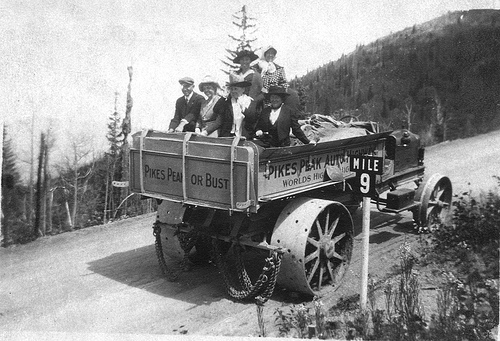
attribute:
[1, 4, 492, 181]
mountains — in background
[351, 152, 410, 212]
sign — mile marker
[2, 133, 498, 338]
dirt road — steep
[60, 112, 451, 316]
truck — large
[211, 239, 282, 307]
chain — large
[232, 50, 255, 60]
hat — large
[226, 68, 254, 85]
hat — large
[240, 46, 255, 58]
hat — floppy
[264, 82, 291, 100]
hat — black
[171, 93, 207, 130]
jacket — dark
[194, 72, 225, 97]
hat — floppy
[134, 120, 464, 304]
truck — large, dump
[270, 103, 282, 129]
shirt — white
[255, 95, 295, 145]
jacket — black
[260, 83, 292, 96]
hat — black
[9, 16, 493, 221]
terrain — in background, rough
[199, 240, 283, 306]
chains — some